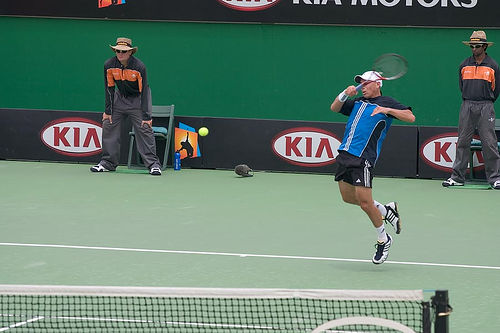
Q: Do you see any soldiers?
A: No, there are no soldiers.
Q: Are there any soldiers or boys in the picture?
A: No, there are no soldiers or boys.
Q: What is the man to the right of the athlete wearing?
A: The man is wearing a hat.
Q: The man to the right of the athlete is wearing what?
A: The man is wearing a hat.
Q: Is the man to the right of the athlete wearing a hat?
A: Yes, the man is wearing a hat.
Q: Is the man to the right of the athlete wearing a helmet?
A: No, the man is wearing a hat.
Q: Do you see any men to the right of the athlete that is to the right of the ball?
A: Yes, there is a man to the right of the athlete.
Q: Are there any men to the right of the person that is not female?
A: Yes, there is a man to the right of the athlete.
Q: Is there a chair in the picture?
A: Yes, there is a chair.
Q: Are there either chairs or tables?
A: Yes, there is a chair.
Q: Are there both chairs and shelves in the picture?
A: No, there is a chair but no shelves.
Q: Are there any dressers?
A: No, there are no dressers.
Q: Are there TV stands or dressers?
A: No, there are no dressers or TV stands.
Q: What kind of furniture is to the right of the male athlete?
A: The piece of furniture is a chair.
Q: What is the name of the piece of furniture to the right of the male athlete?
A: The piece of furniture is a chair.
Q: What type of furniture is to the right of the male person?
A: The piece of furniture is a chair.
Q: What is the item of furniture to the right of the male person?
A: The piece of furniture is a chair.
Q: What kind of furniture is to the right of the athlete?
A: The piece of furniture is a chair.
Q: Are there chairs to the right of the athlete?
A: Yes, there is a chair to the right of the athlete.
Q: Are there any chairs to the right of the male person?
A: Yes, there is a chair to the right of the athlete.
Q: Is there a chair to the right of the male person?
A: Yes, there is a chair to the right of the athlete.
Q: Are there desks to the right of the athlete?
A: No, there is a chair to the right of the athlete.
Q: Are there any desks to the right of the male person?
A: No, there is a chair to the right of the athlete.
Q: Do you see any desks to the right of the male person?
A: No, there is a chair to the right of the athlete.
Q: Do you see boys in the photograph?
A: No, there are no boys.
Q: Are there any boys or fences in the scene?
A: No, there are no boys or fences.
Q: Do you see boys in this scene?
A: No, there are no boys.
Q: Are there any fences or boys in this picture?
A: No, there are no boys or fences.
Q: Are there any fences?
A: No, there are no fences.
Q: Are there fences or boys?
A: No, there are no fences or boys.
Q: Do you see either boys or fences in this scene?
A: No, there are no fences or boys.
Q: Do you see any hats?
A: Yes, there is a hat.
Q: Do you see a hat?
A: Yes, there is a hat.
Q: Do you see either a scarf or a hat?
A: Yes, there is a hat.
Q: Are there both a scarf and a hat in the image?
A: No, there is a hat but no scarves.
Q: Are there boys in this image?
A: No, there are no boys.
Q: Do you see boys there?
A: No, there are no boys.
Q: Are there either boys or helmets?
A: No, there are no boys or helmets.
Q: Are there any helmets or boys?
A: No, there are no boys or helmets.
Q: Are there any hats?
A: Yes, there is a hat.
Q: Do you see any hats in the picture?
A: Yes, there is a hat.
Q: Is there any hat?
A: Yes, there is a hat.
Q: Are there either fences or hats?
A: Yes, there is a hat.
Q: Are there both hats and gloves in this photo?
A: No, there is a hat but no gloves.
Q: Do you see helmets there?
A: No, there are no helmets.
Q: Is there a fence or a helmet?
A: No, there are no helmets or fences.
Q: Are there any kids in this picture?
A: No, there are no kids.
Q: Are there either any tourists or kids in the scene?
A: No, there are no kids or tourists.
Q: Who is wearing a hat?
A: The man is wearing a hat.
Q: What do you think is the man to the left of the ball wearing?
A: The man is wearing a hat.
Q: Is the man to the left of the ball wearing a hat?
A: Yes, the man is wearing a hat.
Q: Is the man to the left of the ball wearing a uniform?
A: No, the man is wearing a hat.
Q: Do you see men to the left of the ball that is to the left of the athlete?
A: Yes, there is a man to the left of the ball.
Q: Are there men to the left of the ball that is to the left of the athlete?
A: Yes, there is a man to the left of the ball.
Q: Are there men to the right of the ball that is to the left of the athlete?
A: No, the man is to the left of the ball.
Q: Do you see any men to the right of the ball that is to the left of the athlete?
A: No, the man is to the left of the ball.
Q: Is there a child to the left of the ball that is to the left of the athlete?
A: No, there is a man to the left of the ball.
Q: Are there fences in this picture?
A: No, there are no fences.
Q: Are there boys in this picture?
A: No, there are no boys.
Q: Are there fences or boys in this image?
A: No, there are no boys or fences.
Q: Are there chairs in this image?
A: Yes, there is a chair.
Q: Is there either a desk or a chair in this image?
A: Yes, there is a chair.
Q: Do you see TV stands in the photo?
A: No, there are no TV stands.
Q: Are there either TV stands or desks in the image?
A: No, there are no TV stands or desks.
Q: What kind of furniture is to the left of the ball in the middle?
A: The piece of furniture is a chair.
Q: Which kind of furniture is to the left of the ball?
A: The piece of furniture is a chair.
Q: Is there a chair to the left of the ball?
A: Yes, there is a chair to the left of the ball.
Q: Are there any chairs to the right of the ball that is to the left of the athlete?
A: No, the chair is to the left of the ball.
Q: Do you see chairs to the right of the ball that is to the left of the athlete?
A: No, the chair is to the left of the ball.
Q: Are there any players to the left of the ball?
A: No, there is a chair to the left of the ball.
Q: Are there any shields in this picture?
A: No, there are no shields.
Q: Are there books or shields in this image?
A: No, there are no shields or books.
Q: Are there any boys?
A: No, there are no boys.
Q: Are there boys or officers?
A: No, there are no boys or officers.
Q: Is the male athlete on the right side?
A: Yes, the athlete is on the right of the image.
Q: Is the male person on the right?
A: Yes, the athlete is on the right of the image.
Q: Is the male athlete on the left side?
A: No, the athlete is on the right of the image.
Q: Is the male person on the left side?
A: No, the athlete is on the right of the image.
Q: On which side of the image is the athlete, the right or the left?
A: The athlete is on the right of the image.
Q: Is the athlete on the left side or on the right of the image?
A: The athlete is on the right of the image.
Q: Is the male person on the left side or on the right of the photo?
A: The athlete is on the right of the image.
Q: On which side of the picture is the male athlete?
A: The athlete is on the right of the image.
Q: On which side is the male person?
A: The athlete is on the right of the image.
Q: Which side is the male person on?
A: The athlete is on the right of the image.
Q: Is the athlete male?
A: Yes, the athlete is male.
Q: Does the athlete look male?
A: Yes, the athlete is male.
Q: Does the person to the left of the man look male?
A: Yes, the athlete is male.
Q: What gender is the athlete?
A: The athlete is male.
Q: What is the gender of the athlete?
A: The athlete is male.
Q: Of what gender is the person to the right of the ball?
A: The athlete is male.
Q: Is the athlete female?
A: No, the athlete is male.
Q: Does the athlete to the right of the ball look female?
A: No, the athlete is male.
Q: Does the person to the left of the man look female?
A: No, the athlete is male.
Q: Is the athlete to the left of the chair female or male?
A: The athlete is male.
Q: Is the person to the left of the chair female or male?
A: The athlete is male.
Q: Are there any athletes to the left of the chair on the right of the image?
A: Yes, there is an athlete to the left of the chair.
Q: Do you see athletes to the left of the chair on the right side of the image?
A: Yes, there is an athlete to the left of the chair.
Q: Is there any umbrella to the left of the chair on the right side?
A: No, there is an athlete to the left of the chair.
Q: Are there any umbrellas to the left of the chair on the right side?
A: No, there is an athlete to the left of the chair.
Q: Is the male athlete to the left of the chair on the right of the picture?
A: Yes, the athlete is to the left of the chair.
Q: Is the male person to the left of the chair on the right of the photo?
A: Yes, the athlete is to the left of the chair.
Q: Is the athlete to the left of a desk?
A: No, the athlete is to the left of the chair.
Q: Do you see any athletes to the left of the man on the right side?
A: Yes, there is an athlete to the left of the man.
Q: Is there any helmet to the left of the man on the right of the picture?
A: No, there is an athlete to the left of the man.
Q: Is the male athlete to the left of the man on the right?
A: Yes, the athlete is to the left of the man.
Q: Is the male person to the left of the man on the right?
A: Yes, the athlete is to the left of the man.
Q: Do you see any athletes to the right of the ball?
A: Yes, there is an athlete to the right of the ball.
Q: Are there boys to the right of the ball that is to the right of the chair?
A: No, there is an athlete to the right of the ball.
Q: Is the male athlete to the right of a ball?
A: Yes, the athlete is to the right of a ball.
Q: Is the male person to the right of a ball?
A: Yes, the athlete is to the right of a ball.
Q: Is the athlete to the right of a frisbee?
A: No, the athlete is to the right of a ball.